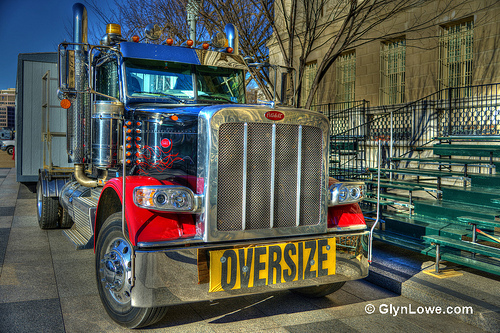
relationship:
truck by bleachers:
[24, 52, 348, 290] [366, 104, 498, 264]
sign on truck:
[204, 243, 342, 289] [24, 52, 348, 290]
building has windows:
[279, 16, 499, 128] [364, 29, 496, 102]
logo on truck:
[263, 108, 302, 126] [24, 52, 348, 290]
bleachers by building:
[366, 104, 498, 264] [279, 16, 499, 128]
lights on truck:
[131, 31, 245, 48] [24, 52, 348, 290]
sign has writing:
[204, 243, 342, 289] [219, 249, 337, 286]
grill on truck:
[226, 138, 330, 235] [24, 52, 348, 290]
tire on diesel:
[98, 231, 155, 309] [69, 106, 242, 278]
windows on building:
[364, 29, 496, 102] [279, 16, 499, 128]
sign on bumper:
[204, 243, 342, 289] [128, 252, 379, 281]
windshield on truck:
[128, 73, 236, 98] [24, 52, 348, 290]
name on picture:
[363, 296, 477, 324] [37, 39, 490, 331]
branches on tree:
[243, 10, 275, 58] [246, 16, 329, 106]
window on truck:
[99, 64, 128, 103] [24, 52, 348, 290]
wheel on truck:
[116, 226, 166, 322] [24, 52, 348, 290]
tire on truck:
[98, 231, 155, 309] [24, 52, 348, 290]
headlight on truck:
[131, 184, 206, 214] [24, 52, 348, 290]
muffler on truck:
[62, 167, 103, 191] [24, 52, 348, 290]